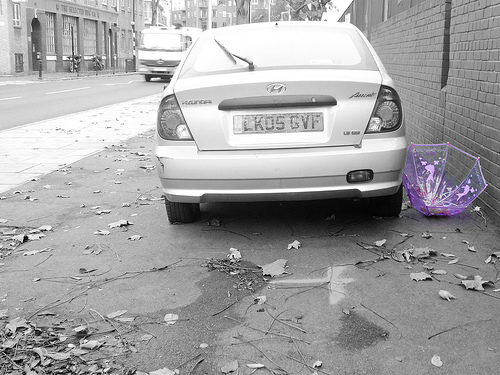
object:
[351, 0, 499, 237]
building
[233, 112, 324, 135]
license plate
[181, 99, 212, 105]
logo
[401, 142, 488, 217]
umbrella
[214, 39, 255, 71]
wiper blade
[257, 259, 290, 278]
leaves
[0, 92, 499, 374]
ground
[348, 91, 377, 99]
sign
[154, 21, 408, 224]
car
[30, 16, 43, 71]
archway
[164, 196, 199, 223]
tires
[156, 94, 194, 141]
tail lights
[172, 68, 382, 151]
trunk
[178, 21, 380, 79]
back window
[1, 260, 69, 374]
street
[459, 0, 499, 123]
wall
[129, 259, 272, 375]
oil spots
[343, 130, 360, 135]
lettering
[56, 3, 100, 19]
lettering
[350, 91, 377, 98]
lettering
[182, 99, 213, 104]
lettering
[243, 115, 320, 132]
lettering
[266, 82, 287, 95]
logo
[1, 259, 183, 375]
twigs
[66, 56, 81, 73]
bike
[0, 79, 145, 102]
stripe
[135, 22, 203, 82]
bus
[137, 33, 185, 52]
windshield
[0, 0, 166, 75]
building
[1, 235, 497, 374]
concrete